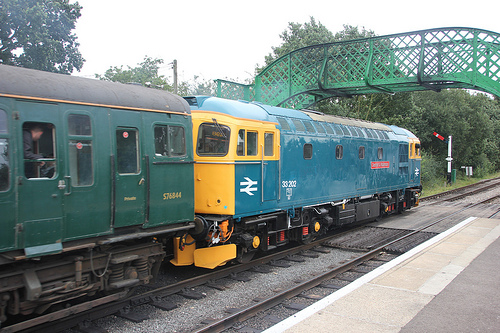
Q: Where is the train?
A: Tracks.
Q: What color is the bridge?
A: Green.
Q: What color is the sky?
A: White.